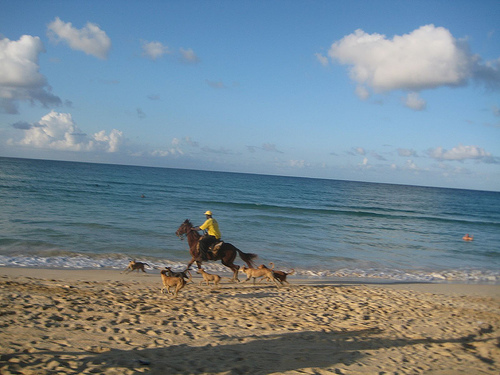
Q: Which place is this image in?
A: It is at the ocean.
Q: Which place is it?
A: It is an ocean.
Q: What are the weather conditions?
A: It is partly cloudy.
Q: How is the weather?
A: It is partly cloudy.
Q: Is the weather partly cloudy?
A: Yes, it is partly cloudy.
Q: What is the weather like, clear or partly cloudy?
A: It is partly cloudy.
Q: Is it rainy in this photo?
A: No, it is partly cloudy.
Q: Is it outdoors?
A: Yes, it is outdoors.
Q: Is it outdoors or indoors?
A: It is outdoors.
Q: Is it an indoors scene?
A: No, it is outdoors.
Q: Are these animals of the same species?
A: No, there are both horses and dogs.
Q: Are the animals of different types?
A: Yes, they are horses and dogs.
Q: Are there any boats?
A: No, there are no boats.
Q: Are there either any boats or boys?
A: No, there are no boats or boys.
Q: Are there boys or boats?
A: No, there are no boats or boys.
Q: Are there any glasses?
A: No, there are no glasses.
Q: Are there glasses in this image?
A: No, there are no glasses.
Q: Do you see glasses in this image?
A: No, there are no glasses.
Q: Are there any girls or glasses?
A: No, there are no glasses or girls.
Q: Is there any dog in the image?
A: Yes, there is a dog.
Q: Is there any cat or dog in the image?
A: Yes, there is a dog.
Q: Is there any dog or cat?
A: Yes, there is a dog.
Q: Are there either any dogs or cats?
A: Yes, there is a dog.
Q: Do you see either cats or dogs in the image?
A: Yes, there is a dog.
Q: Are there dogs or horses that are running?
A: Yes, the dog is running.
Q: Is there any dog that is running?
A: Yes, there is a dog that is running.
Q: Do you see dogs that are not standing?
A: Yes, there is a dog that is running .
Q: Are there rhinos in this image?
A: No, there are no rhinos.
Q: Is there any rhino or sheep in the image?
A: No, there are no rhinos or sheep.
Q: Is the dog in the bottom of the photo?
A: Yes, the dog is in the bottom of the image.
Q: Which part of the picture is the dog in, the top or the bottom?
A: The dog is in the bottom of the image.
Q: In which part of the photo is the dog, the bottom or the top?
A: The dog is in the bottom of the image.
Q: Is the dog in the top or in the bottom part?
A: The dog is in the bottom of the image.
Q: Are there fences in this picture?
A: No, there are no fences.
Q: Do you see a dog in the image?
A: Yes, there are dogs.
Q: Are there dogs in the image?
A: Yes, there are dogs.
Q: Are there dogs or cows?
A: Yes, there are dogs.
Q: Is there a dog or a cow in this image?
A: Yes, there are dogs.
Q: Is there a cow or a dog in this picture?
A: Yes, there are dogs.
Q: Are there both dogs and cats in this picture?
A: No, there are dogs but no cats.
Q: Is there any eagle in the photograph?
A: No, there are no eagles.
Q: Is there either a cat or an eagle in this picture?
A: No, there are no eagles or cats.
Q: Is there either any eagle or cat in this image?
A: No, there are no eagles or cats.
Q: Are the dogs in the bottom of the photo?
A: Yes, the dogs are in the bottom of the image.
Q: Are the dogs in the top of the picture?
A: No, the dogs are in the bottom of the image.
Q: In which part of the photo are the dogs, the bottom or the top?
A: The dogs are in the bottom of the image.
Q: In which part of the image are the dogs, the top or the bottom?
A: The dogs are in the bottom of the image.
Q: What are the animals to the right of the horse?
A: The animals are dogs.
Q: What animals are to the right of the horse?
A: The animals are dogs.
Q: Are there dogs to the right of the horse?
A: Yes, there are dogs to the right of the horse.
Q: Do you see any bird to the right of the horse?
A: No, there are dogs to the right of the horse.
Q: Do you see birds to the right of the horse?
A: No, there are dogs to the right of the horse.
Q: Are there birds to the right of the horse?
A: No, there are dogs to the right of the horse.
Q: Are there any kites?
A: No, there are no kites.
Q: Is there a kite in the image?
A: No, there are no kites.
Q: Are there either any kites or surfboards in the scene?
A: No, there are no kites or surfboards.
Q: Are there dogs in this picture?
A: Yes, there is a dog.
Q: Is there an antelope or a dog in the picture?
A: Yes, there is a dog.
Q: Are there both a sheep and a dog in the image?
A: No, there is a dog but no sheep.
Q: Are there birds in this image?
A: No, there are no birds.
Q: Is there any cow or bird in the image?
A: No, there are no birds or cows.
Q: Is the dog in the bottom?
A: Yes, the dog is in the bottom of the image.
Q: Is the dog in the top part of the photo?
A: No, the dog is in the bottom of the image.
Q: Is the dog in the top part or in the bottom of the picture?
A: The dog is in the bottom of the image.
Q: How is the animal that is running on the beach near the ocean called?
A: The animal is a dog.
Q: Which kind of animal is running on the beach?
A: The animal is a dog.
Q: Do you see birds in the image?
A: No, there are no birds.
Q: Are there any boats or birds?
A: No, there are no birds or boats.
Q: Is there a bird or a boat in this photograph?
A: No, there are no birds or boats.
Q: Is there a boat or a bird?
A: No, there are no birds or boats.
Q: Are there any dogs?
A: Yes, there are dogs.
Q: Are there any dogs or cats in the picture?
A: Yes, there are dogs.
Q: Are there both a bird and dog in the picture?
A: No, there are dogs but no birds.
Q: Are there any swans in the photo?
A: No, there are no swans.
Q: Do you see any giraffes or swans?
A: No, there are no swans or giraffes.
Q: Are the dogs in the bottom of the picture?
A: Yes, the dogs are in the bottom of the image.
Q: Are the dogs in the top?
A: No, the dogs are in the bottom of the image.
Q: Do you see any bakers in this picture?
A: No, there are no bakers.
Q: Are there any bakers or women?
A: No, there are no bakers or women.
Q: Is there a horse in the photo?
A: Yes, there is a horse.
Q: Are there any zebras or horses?
A: Yes, there is a horse.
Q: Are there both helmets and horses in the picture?
A: No, there is a horse but no helmets.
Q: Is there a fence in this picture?
A: No, there are no fences.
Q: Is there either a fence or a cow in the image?
A: No, there are no fences or cows.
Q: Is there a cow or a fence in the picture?
A: No, there are no fences or cows.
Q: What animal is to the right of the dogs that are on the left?
A: The animal is a horse.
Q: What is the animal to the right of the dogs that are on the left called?
A: The animal is a horse.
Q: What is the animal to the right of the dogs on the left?
A: The animal is a horse.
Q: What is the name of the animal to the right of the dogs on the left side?
A: The animal is a horse.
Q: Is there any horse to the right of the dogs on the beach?
A: Yes, there is a horse to the right of the dogs.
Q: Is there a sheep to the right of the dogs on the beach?
A: No, there is a horse to the right of the dogs.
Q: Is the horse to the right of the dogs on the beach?
A: Yes, the horse is to the right of the dogs.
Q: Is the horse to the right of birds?
A: No, the horse is to the right of the dogs.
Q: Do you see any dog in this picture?
A: Yes, there are dogs.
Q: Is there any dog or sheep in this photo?
A: Yes, there are dogs.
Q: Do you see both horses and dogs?
A: Yes, there are both dogs and a horse.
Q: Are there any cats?
A: No, there are no cats.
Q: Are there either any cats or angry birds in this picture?
A: No, there are no cats or angry birds.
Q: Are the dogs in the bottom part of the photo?
A: Yes, the dogs are in the bottom of the image.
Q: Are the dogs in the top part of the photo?
A: No, the dogs are in the bottom of the image.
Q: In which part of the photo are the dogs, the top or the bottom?
A: The dogs are in the bottom of the image.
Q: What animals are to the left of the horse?
A: The animals are dogs.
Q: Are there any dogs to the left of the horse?
A: Yes, there are dogs to the left of the horse.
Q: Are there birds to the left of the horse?
A: No, there are dogs to the left of the horse.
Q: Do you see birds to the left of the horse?
A: No, there are dogs to the left of the horse.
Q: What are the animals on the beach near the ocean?
A: The animals are dogs.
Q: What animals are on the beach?
A: The animals are dogs.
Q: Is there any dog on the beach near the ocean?
A: Yes, there are dogs on the beach.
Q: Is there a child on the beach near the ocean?
A: No, there are dogs on the beach.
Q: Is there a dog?
A: Yes, there are dogs.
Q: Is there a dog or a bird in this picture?
A: Yes, there are dogs.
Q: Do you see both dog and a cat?
A: No, there are dogs but no cats.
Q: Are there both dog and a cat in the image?
A: No, there are dogs but no cats.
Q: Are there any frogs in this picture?
A: No, there are no frogs.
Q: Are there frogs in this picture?
A: No, there are no frogs.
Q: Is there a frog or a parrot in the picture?
A: No, there are no frogs or parrots.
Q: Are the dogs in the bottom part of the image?
A: Yes, the dogs are in the bottom of the image.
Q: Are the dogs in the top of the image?
A: No, the dogs are in the bottom of the image.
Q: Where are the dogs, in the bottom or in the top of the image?
A: The dogs are in the bottom of the image.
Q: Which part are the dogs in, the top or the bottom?
A: The dogs are in the bottom of the image.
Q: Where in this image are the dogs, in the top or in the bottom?
A: The dogs are in the bottom of the image.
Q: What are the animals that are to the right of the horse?
A: The animals are dogs.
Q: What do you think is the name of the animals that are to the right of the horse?
A: The animals are dogs.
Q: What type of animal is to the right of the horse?
A: The animals are dogs.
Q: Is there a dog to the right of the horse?
A: Yes, there are dogs to the right of the horse.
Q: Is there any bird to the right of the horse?
A: No, there are dogs to the right of the horse.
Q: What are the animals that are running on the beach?
A: The animals are dogs.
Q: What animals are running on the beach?
A: The animals are dogs.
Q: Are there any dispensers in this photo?
A: No, there are no dispensers.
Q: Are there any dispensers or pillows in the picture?
A: No, there are no dispensers or pillows.